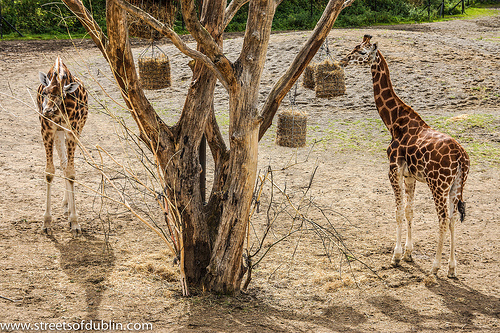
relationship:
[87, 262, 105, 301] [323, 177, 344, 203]
shadows on ground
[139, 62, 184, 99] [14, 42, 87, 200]
hay for giraffe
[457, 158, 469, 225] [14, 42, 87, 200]
tail of giraffe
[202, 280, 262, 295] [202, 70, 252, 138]
base of tree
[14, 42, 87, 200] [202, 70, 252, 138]
giraffe next to tree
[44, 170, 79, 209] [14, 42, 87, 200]
legs of giraffe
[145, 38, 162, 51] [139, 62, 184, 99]
wire holding hay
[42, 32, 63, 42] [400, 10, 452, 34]
grass of pasture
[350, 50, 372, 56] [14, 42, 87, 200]
eye of giraffe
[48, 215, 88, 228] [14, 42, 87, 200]
feet of giraffe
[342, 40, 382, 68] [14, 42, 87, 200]
head of giraffe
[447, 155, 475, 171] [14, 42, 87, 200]
tail of giraffe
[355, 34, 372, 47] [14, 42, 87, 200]
horns of giraffe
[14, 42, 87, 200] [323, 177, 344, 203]
giraffe on ground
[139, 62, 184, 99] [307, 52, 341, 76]
hay in bag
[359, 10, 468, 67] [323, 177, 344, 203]
spots on ground